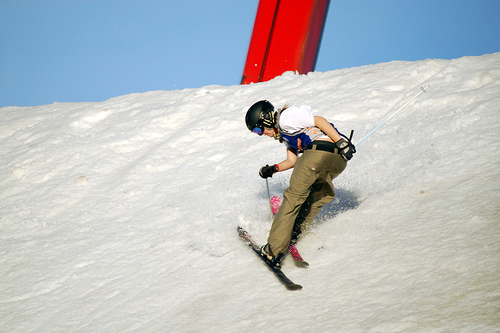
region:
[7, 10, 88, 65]
this is the sky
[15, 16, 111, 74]
the sky is blue in color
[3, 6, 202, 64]
the sky is clear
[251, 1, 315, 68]
this is an object on the snow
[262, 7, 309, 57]
the object is red in color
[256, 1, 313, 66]
the object is big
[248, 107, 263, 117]
this is a helmet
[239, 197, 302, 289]
these are some surfboards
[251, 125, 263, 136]
these are surfing goggles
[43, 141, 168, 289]
the snow is white in color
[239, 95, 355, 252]
this is a man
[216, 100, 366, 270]
the man is skating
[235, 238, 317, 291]
the man is wearing skiis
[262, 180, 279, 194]
the right hand is carrying stick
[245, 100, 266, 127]
the man is wearing a helmet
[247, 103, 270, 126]
the helmet is black in color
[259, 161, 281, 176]
the glove is black in color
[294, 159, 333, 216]
the trousers is green in color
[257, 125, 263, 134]
the goggles is blue in color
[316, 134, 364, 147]
the left hand is back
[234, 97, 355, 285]
a man wearing skis on the hill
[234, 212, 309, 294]
the skis the man is wearing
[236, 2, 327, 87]
a red pole on the top of the hill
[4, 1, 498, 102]
the blue sky above the hill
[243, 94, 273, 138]
the helmet the man is wearing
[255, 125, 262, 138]
the goggles on the man's face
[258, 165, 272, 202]
the ski pole the man his holding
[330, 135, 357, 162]
the glove on the man's hand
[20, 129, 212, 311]
a big fat pile of snow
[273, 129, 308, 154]
a blue shirt the man is wearing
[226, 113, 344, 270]
The person is skiing.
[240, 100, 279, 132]
The helmet is black.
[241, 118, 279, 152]
The goggles are blue.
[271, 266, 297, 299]
The ski is black.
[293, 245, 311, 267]
The ski is pink.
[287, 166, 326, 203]
The pants are khaki.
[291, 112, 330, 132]
The shirt is white.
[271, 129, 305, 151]
The vest is blue.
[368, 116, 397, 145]
The ski stick is white.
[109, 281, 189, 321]
There is snow on the ground.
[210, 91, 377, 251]
the man is snow skating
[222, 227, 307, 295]
he is wearing skiis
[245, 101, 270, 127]
the man is wearing helmet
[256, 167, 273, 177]
the right hand is wearing gloves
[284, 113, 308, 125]
the shirt is white in color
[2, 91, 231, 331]
snow is allover the place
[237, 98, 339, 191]
the man is bent